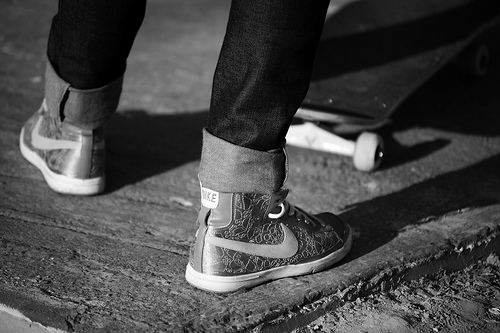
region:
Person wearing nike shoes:
[177, 169, 374, 291]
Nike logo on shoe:
[203, 221, 323, 256]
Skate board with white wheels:
[242, 34, 474, 199]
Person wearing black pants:
[221, 7, 339, 224]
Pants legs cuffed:
[183, 100, 293, 194]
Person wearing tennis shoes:
[16, 94, 116, 203]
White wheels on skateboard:
[339, 133, 396, 165]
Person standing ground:
[157, 208, 386, 310]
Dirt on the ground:
[385, 279, 469, 331]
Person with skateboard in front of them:
[276, 38, 406, 166]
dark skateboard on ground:
[278, 1, 455, 141]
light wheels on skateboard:
[292, 116, 403, 194]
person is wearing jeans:
[55, 8, 335, 164]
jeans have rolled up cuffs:
[189, 105, 282, 202]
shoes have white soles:
[182, 196, 384, 309]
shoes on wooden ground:
[72, 155, 342, 317]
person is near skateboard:
[178, 1, 454, 308]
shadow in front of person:
[80, 62, 306, 194]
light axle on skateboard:
[290, 118, 358, 172]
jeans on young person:
[62, 18, 309, 224]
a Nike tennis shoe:
[178, 177, 360, 295]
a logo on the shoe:
[201, 217, 309, 264]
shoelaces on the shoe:
[281, 192, 329, 232]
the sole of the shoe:
[181, 215, 361, 294]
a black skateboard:
[276, 0, 497, 175]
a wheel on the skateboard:
[346, 127, 389, 179]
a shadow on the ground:
[325, 149, 497, 274]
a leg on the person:
[193, 0, 331, 199]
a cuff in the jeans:
[191, 120, 303, 197]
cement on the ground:
[1, 0, 498, 327]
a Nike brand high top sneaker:
[183, 176, 355, 298]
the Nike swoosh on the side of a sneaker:
[210, 212, 309, 259]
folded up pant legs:
[27, 47, 292, 194]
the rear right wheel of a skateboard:
[343, 126, 388, 173]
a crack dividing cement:
[377, 227, 494, 319]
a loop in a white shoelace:
[264, 198, 291, 222]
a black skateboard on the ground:
[281, 17, 436, 162]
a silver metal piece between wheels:
[290, 116, 352, 160]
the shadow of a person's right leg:
[330, 161, 488, 238]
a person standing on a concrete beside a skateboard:
[24, 5, 469, 289]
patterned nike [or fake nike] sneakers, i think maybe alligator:
[6, 96, 357, 301]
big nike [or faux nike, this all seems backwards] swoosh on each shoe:
[20, 105, 300, 265]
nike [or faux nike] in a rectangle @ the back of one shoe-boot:
[195, 180, 215, 205]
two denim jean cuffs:
[25, 55, 280, 195]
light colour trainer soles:
[17, 122, 357, 327]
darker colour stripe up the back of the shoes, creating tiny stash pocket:
[70, 119, 236, 299]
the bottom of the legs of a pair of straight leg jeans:
[38, 0, 326, 197]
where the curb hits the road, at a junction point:
[0, 227, 499, 332]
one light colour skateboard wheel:
[350, 128, 389, 177]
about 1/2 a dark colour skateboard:
[285, 0, 499, 132]